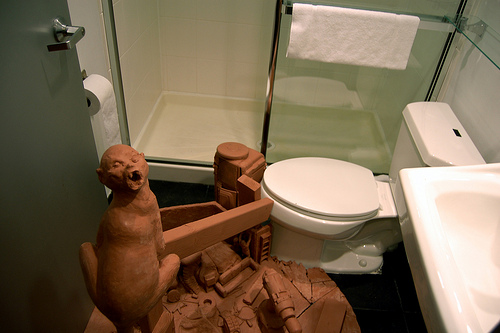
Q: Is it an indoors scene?
A: Yes, it is indoors.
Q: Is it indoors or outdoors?
A: It is indoors.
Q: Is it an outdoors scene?
A: No, it is indoors.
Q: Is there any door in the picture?
A: Yes, there is a door.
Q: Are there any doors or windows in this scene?
A: Yes, there is a door.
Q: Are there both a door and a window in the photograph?
A: No, there is a door but no windows.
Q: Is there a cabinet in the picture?
A: No, there are no cabinets.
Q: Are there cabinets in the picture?
A: No, there are no cabinets.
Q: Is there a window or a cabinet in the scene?
A: No, there are no cabinets or windows.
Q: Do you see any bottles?
A: No, there are no bottles.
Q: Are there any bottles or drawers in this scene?
A: No, there are no bottles or drawers.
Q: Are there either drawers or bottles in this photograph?
A: No, there are no bottles or drawers.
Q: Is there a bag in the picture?
A: No, there are no bags.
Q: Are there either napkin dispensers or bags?
A: No, there are no bags or napkin dispensers.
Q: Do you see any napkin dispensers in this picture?
A: No, there are no napkin dispensers.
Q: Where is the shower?
A: The shower is in the bathroom.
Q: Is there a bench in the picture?
A: No, there are no benches.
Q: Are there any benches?
A: No, there are no benches.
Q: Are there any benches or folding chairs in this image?
A: No, there are no benches or folding chairs.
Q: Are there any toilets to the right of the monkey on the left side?
A: Yes, there is a toilet to the right of the monkey.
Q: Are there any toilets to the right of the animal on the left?
A: Yes, there is a toilet to the right of the monkey.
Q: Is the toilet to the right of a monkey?
A: Yes, the toilet is to the right of a monkey.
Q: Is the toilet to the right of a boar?
A: No, the toilet is to the right of a monkey.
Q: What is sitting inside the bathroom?
A: The toilet is sitting inside the bathroom.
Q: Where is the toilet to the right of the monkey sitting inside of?
A: The toilet is sitting inside the bathroom.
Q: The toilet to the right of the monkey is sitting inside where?
A: The toilet is sitting inside the bathroom.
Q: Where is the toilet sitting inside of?
A: The toilet is sitting inside the bathroom.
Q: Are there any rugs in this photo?
A: No, there are no rugs.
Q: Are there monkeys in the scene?
A: Yes, there is a monkey.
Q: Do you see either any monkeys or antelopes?
A: Yes, there is a monkey.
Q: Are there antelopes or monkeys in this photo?
A: Yes, there is a monkey.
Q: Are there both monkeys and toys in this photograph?
A: No, there is a monkey but no toys.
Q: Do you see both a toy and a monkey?
A: No, there is a monkey but no toys.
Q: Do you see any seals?
A: No, there are no seals.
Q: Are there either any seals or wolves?
A: No, there are no seals or wolves.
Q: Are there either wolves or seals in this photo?
A: No, there are no seals or wolves.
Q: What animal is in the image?
A: The animal is a monkey.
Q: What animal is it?
A: The animal is a monkey.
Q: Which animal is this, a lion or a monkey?
A: That is a monkey.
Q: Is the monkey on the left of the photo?
A: Yes, the monkey is on the left of the image.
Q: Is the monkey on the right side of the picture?
A: No, the monkey is on the left of the image.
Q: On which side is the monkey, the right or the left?
A: The monkey is on the left of the image.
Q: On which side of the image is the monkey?
A: The monkey is on the left of the image.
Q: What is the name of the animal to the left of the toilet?
A: The animal is a monkey.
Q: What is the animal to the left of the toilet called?
A: The animal is a monkey.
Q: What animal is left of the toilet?
A: The animal is a monkey.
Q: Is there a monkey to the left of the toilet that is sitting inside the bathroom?
A: Yes, there is a monkey to the left of the toilet.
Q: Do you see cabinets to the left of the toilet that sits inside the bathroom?
A: No, there is a monkey to the left of the toilet.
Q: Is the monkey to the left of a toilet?
A: Yes, the monkey is to the left of a toilet.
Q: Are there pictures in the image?
A: No, there are no pictures.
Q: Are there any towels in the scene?
A: Yes, there is a towel.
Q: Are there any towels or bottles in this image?
A: Yes, there is a towel.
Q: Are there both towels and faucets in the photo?
A: No, there is a towel but no faucets.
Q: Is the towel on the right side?
A: Yes, the towel is on the right of the image.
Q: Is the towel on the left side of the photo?
A: No, the towel is on the right of the image.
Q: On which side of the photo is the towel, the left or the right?
A: The towel is on the right of the image.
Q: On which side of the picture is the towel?
A: The towel is on the right of the image.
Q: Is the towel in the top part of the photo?
A: Yes, the towel is in the top of the image.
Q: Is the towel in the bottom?
A: No, the towel is in the top of the image.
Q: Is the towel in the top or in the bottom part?
A: The towel is in the top of the image.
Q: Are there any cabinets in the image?
A: No, there are no cabinets.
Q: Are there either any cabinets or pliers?
A: No, there are no cabinets or pliers.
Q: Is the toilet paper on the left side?
A: Yes, the toilet paper is on the left of the image.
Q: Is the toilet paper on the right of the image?
A: No, the toilet paper is on the left of the image.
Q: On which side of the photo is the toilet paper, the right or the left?
A: The toilet paper is on the left of the image.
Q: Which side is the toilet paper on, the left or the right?
A: The toilet paper is on the left of the image.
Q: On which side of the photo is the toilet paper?
A: The toilet paper is on the left of the image.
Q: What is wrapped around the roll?
A: The toilet paper is wrapped around the roll.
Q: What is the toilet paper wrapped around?
A: The toilet paper is wrapped around the toilet roll.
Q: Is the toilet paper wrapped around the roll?
A: Yes, the toilet paper is wrapped around the roll.